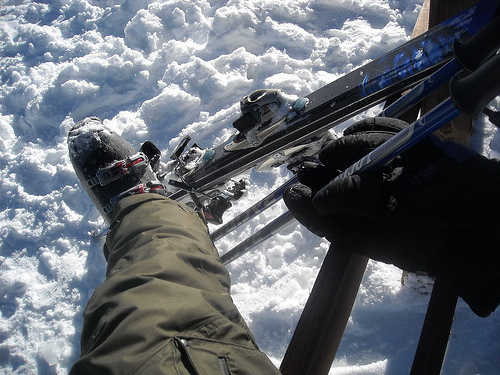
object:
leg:
[64, 122, 282, 375]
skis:
[121, 11, 484, 261]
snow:
[0, 0, 453, 373]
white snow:
[103, 10, 238, 85]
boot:
[67, 121, 172, 238]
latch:
[87, 153, 147, 185]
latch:
[104, 182, 166, 213]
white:
[324, 14, 376, 59]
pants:
[68, 192, 283, 374]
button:
[178, 338, 189, 347]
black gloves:
[285, 117, 500, 318]